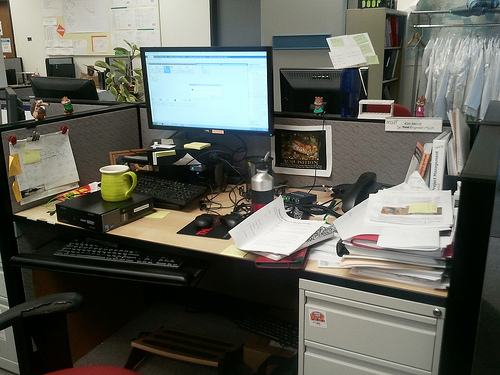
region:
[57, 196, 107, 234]
this is the cpu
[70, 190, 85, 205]
the cpu is black in color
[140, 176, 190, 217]
this is the keyboard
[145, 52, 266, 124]
this is the screen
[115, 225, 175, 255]
this is the table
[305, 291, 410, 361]
this is a drawer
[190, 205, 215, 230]
this is the mouse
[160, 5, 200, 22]
this is the wall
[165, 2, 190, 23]
the wall is white in color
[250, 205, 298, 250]
this is a paper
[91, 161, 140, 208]
light green pottery type drinking mug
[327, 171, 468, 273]
tall stack of papers on desk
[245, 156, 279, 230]
stainless steel drinking container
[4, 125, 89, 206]
calendar with sticky notes on it attached to side of cubicle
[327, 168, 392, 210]
black desk style telephone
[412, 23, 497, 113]
white uniform tops or jackets hanging on hangers with plastic to protect them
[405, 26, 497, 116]
many white tops on clothes hangers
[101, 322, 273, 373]
low footstool under desk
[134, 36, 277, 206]
computer key board and flat screen monitor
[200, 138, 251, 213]
tangle of wires for electronics on desk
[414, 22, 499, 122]
White lab smocks hanging on hangers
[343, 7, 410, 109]
Light colored shelving unit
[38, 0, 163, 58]
A bulletin board with papers on it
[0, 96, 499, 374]
Gray and black office cubicle dividers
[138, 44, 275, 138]
A flat screen computer minotor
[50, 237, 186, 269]
A black computer keyboard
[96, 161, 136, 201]
A lime green ceramic coffee cup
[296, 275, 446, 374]
Locked office desk drawers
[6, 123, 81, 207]
A calendar with Post-it notes on it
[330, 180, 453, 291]
A stack of papers sitting on a desk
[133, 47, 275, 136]
A black framed flatscreen computer monitor.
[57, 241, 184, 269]
A black computer keyboard.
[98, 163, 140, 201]
A green coffee mug.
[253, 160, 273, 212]
A silver, black, and red water bottle.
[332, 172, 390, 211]
A black telephone.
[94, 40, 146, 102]
A green plant.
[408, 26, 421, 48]
A wooden hanger.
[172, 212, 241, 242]
A black and red mousepad.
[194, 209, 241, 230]
Two black computer mouses.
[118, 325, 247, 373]
A brown foot rest.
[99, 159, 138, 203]
a green coffee mug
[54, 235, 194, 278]
a black computer keyboard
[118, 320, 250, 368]
a wood foot stool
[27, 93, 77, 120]
a pair of figurines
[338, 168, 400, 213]
a black office phone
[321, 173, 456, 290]
a stack of paperwork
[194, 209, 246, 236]
a pair of black computer mouses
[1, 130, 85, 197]
a white calendar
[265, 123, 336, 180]
a picture posted on a wall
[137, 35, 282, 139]
a computer monitor